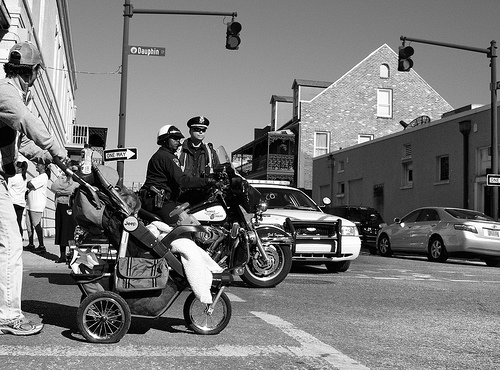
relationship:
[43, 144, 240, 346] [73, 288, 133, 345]
stroller has back wheel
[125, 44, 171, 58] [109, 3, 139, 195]
street sign on pole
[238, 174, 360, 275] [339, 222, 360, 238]
car has headlight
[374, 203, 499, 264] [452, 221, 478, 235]
car has tail light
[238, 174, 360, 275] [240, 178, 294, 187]
car has light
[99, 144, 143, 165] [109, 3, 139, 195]
sign on pole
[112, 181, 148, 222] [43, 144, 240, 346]
child inside of stroller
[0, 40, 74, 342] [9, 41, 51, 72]
person wearing baseball cap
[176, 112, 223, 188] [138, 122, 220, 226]
cop standing next to cop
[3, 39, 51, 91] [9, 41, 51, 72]
head wearing baseball cap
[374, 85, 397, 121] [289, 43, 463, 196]
window on building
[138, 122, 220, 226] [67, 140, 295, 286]
cop on top of motorcycle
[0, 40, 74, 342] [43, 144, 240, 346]
person pushing stroller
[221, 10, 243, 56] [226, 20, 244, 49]
lights have traffic lights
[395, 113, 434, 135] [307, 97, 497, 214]
satellite dish on top of building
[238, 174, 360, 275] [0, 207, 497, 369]
car on street